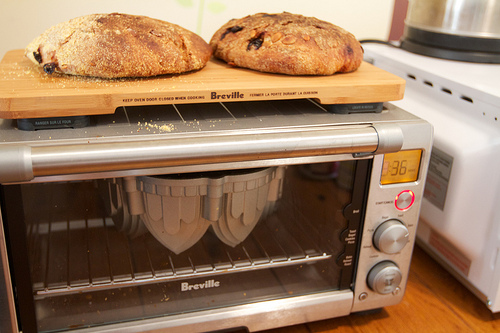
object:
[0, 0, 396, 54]
wall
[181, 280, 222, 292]
logo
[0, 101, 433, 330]
appliance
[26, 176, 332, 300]
grill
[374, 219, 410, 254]
knobs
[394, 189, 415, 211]
button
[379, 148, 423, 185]
window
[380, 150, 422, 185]
light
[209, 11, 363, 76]
good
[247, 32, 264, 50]
raisins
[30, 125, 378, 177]
handle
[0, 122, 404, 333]
door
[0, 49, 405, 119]
board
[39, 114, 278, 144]
crumbs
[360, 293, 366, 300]
button